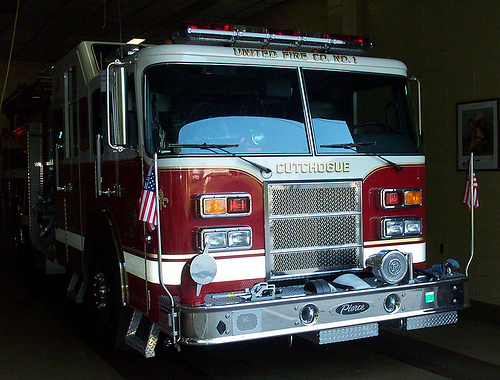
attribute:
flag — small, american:
[139, 162, 162, 226]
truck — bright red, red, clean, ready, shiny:
[1, 26, 472, 345]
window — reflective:
[145, 63, 421, 157]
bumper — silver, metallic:
[177, 271, 474, 343]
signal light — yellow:
[202, 196, 225, 212]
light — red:
[227, 196, 250, 213]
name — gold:
[233, 45, 358, 66]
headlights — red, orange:
[197, 191, 422, 245]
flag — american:
[465, 151, 480, 211]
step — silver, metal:
[124, 313, 160, 357]